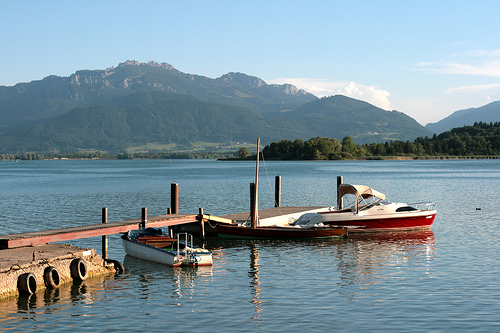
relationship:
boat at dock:
[304, 177, 447, 234] [0, 213, 233, 265]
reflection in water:
[247, 245, 265, 273] [3, 157, 496, 326]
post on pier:
[171, 166, 346, 223] [22, 183, 386, 271]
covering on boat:
[338, 184, 383, 201] [303, 186, 435, 230]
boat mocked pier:
[120, 228, 213, 270] [0, 172, 342, 274]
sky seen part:
[0, 0, 499, 60] [330, 17, 360, 46]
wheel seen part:
[45, 267, 62, 288] [48, 281, 57, 288]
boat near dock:
[120, 228, 213, 268] [0, 204, 225, 265]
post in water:
[249, 182, 258, 228] [219, 262, 376, 316]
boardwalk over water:
[8, 207, 333, 250] [3, 152, 498, 212]